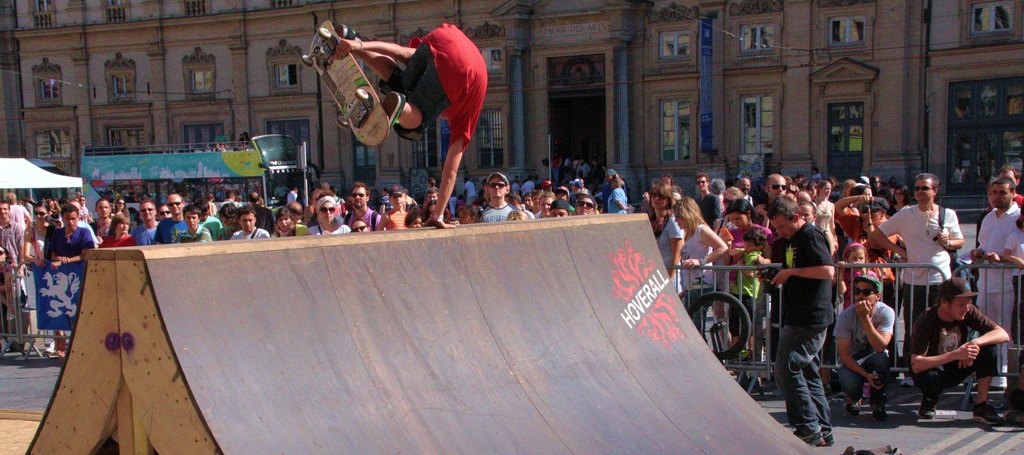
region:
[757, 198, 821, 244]
the head of a man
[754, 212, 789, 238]
the face of a man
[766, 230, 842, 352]
the shirt of a man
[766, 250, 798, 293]
the hand of a man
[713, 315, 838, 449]
the pants of a man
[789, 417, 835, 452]
the shoes of a man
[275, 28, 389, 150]
a skateboard that is brown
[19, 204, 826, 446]
the ramp is wooden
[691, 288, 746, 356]
the wheel of the bicycle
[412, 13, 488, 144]
the tee shirt is red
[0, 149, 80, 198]
the canopy is white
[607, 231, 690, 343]
the image on the ramp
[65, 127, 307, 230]
the light green double-decker vehicle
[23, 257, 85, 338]
the blue and white banner on the railing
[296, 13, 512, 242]
the person is skateboarding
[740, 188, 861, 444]
the man holding the camera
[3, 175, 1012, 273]
the large crowd of people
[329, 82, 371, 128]
wheels of the skateboard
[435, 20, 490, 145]
the shirt is red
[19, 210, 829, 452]
the wooden ramp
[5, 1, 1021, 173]
building behind the people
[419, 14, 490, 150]
THE MAN IS WEARING A RED SHIRT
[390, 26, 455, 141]
THE MAN IS WEARING BLACK SHORTS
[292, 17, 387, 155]
THIS IS A SKATEBOARD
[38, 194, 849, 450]
THIS IS A RAMP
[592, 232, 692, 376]
THE LOGO IS ON THE RAMP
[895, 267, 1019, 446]
THE MAN IS SQUATING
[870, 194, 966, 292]
THE MAN IS WEARING A WHITE SHIRT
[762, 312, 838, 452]
THE MAN IS WEARING JEANS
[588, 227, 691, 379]
red and white writting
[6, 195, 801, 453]
a wood skating ramp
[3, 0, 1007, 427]
people watching person skating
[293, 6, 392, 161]
bottom of a skate board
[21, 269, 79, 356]
a blue and white sign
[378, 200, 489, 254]
a hand touching ramp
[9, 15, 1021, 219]
The building in the background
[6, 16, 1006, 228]
A building in the background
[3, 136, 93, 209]
The white tent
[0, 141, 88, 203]
A white tent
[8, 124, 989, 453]
The crowd of people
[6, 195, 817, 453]
The skateboard ramp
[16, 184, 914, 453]
A skateboard ramp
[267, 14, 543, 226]
The person skateboarding wearing red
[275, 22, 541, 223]
A person skateboarding wearing red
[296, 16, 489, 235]
man in red shirt with skateboard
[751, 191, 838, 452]
man who is filming with black shirt and jeans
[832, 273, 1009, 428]
two men in baseball caps squatting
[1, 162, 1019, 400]
large crowd of onlookers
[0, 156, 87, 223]
white canopy on poles